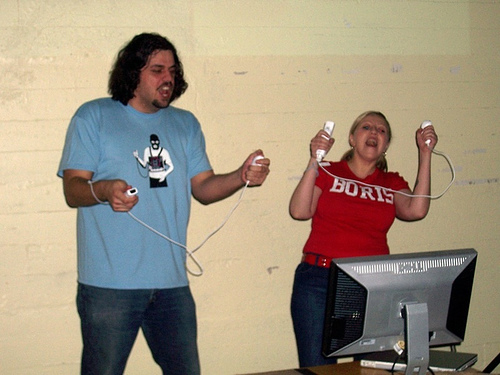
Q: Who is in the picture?
A: A man and woman.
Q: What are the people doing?
A: Playing wii.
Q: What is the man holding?
A: A wii.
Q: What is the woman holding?
A: A wii.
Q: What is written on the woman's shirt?
A: BORIS.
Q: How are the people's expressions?
A: Excited.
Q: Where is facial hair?
A: On man's face.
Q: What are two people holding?
A: Game controllers.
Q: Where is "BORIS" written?
A: On woman's shirt.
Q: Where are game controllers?
A: In people's hands.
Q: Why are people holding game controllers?
A: To play a video game.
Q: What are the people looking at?
A: Computer screen.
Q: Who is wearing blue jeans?
A: Man and woman.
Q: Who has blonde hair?
A: The woman.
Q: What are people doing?
A: Playing video games.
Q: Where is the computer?
A: On a table.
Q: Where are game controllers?
A: In people's hands.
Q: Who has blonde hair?
A: The woman.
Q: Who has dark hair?
A: The man.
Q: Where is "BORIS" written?
A: On woman's shirt.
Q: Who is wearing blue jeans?
A: Man and woman.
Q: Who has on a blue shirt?
A: The man.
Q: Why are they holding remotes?
A: They are playing a game.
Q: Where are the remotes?
A: In their hands.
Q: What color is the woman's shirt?
A: Red.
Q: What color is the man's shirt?
A: Blue.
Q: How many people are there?
A: Two.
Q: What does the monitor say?
A: Dell.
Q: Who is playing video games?
A: Two people.